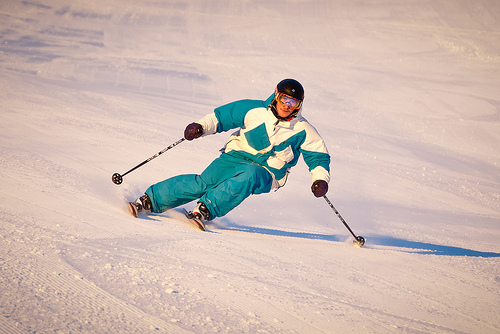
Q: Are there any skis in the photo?
A: Yes, there are skis.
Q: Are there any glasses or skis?
A: Yes, there are skis.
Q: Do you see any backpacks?
A: No, there are no backpacks.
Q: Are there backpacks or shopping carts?
A: No, there are no backpacks or shopping carts.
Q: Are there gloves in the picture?
A: Yes, there are gloves.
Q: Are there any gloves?
A: Yes, there are gloves.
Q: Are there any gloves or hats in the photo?
A: Yes, there are gloves.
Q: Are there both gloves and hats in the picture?
A: Yes, there are both gloves and a hat.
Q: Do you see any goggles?
A: Yes, there are goggles.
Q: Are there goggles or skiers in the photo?
A: Yes, there are goggles.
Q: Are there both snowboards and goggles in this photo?
A: No, there are goggles but no snowboards.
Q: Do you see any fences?
A: No, there are no fences.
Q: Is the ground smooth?
A: Yes, the ground is smooth.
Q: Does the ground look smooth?
A: Yes, the ground is smooth.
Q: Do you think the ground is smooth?
A: Yes, the ground is smooth.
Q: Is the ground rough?
A: No, the ground is smooth.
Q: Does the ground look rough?
A: No, the ground is smooth.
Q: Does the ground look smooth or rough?
A: The ground is smooth.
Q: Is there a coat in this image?
A: Yes, there is a coat.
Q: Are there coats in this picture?
A: Yes, there is a coat.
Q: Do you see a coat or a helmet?
A: Yes, there is a coat.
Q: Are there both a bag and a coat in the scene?
A: No, there is a coat but no bags.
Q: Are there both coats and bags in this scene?
A: No, there is a coat but no bags.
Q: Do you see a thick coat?
A: Yes, there is a thick coat.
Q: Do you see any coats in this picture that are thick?
A: Yes, there is a coat that is thick.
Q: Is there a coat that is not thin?
A: Yes, there is a thick coat.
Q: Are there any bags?
A: No, there are no bags.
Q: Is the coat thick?
A: Yes, the coat is thick.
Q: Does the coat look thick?
A: Yes, the coat is thick.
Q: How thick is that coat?
A: The coat is thick.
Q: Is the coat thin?
A: No, the coat is thick.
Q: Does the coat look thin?
A: No, the coat is thick.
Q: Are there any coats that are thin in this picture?
A: No, there is a coat but it is thick.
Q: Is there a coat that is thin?
A: No, there is a coat but it is thick.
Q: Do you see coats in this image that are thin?
A: No, there is a coat but it is thick.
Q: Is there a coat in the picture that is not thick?
A: No, there is a coat but it is thick.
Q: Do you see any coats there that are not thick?
A: No, there is a coat but it is thick.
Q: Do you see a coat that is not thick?
A: No, there is a coat but it is thick.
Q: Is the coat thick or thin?
A: The coat is thick.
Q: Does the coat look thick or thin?
A: The coat is thick.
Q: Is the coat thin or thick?
A: The coat is thick.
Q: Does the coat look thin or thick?
A: The coat is thick.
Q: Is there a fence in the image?
A: No, there are no fences.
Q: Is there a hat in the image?
A: Yes, there is a hat.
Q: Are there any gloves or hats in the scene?
A: Yes, there is a hat.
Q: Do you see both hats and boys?
A: No, there is a hat but no boys.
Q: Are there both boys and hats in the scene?
A: No, there is a hat but no boys.